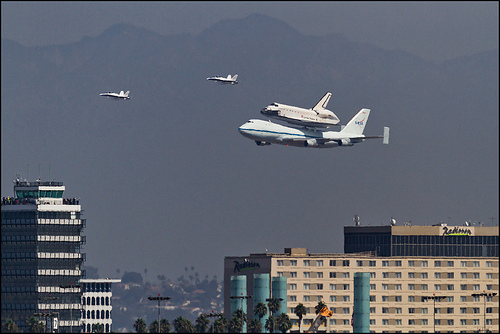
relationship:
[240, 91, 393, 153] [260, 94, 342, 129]
airplane carrying a space shuttle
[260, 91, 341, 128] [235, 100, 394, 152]
airplane sitting on air plane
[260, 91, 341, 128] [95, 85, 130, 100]
airplane sitting on air plane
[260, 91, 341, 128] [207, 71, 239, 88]
airplane sitting on air plane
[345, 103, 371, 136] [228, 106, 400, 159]
fin on plane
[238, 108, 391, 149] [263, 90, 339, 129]
airplane with shuttle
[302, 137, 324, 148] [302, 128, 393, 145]
engine under wing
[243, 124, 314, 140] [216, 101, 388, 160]
line runs across plane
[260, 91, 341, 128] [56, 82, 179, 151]
airplane on plane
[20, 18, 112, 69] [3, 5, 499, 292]
white clouds in sky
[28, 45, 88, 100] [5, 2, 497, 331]
white clouds in sky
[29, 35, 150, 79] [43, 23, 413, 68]
white clouds in sky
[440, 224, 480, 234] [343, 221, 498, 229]
hotel name on roof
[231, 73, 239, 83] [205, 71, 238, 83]
tail fin on a plane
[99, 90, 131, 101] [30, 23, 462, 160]
air plane flying in sky